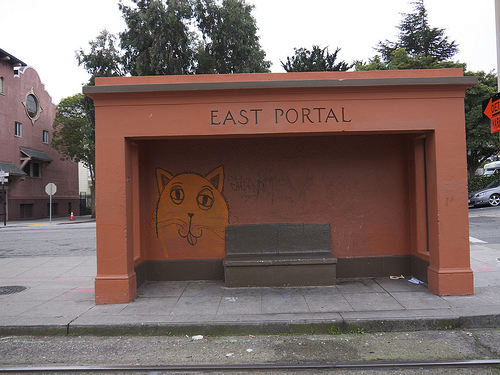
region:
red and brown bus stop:
[88, 66, 478, 300]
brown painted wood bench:
[221, 222, 336, 280]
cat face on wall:
[153, 169, 231, 251]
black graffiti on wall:
[227, 169, 302, 214]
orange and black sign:
[483, 92, 499, 131]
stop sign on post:
[45, 182, 57, 219]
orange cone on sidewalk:
[69, 210, 74, 221]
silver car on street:
[471, 185, 498, 207]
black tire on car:
[489, 193, 499, 207]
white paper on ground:
[409, 276, 422, 288]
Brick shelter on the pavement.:
[77, 57, 481, 308]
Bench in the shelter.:
[215, 215, 343, 290]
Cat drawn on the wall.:
[147, 158, 230, 260]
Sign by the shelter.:
[481, 86, 498, 131]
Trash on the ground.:
[385, 263, 427, 291]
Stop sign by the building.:
[40, 178, 60, 224]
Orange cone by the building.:
[66, 206, 77, 222]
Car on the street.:
[473, 167, 498, 203]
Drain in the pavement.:
[0, 277, 33, 301]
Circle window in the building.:
[19, 85, 44, 126]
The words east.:
[201, 107, 273, 128]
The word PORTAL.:
[269, 105, 355, 129]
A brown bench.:
[217, 219, 342, 294]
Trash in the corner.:
[385, 270, 422, 291]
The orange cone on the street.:
[65, 210, 78, 220]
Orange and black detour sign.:
[483, 97, 498, 128]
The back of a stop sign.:
[41, 181, 63, 221]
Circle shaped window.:
[17, 83, 47, 128]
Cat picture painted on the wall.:
[150, 166, 230, 278]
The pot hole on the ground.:
[0, 282, 32, 304]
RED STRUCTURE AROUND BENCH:
[96, 70, 467, 310]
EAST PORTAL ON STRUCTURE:
[196, 104, 364, 134]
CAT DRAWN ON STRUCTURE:
[150, 159, 234, 261]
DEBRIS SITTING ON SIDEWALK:
[392, 265, 432, 296]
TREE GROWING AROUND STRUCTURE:
[84, 10, 282, 80]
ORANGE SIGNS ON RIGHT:
[462, 98, 498, 125]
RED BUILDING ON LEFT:
[1, 65, 90, 212]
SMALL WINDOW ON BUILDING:
[10, 122, 25, 136]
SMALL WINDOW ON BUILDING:
[35, 130, 52, 145]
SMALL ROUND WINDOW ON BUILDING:
[25, 87, 39, 115]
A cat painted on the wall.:
[145, 163, 229, 262]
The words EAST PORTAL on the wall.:
[201, 101, 353, 131]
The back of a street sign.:
[42, 179, 64, 215]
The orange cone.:
[66, 210, 78, 222]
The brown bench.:
[212, 221, 354, 290]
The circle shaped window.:
[20, 91, 50, 123]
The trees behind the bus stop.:
[102, 0, 452, 69]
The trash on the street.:
[179, 335, 246, 366]